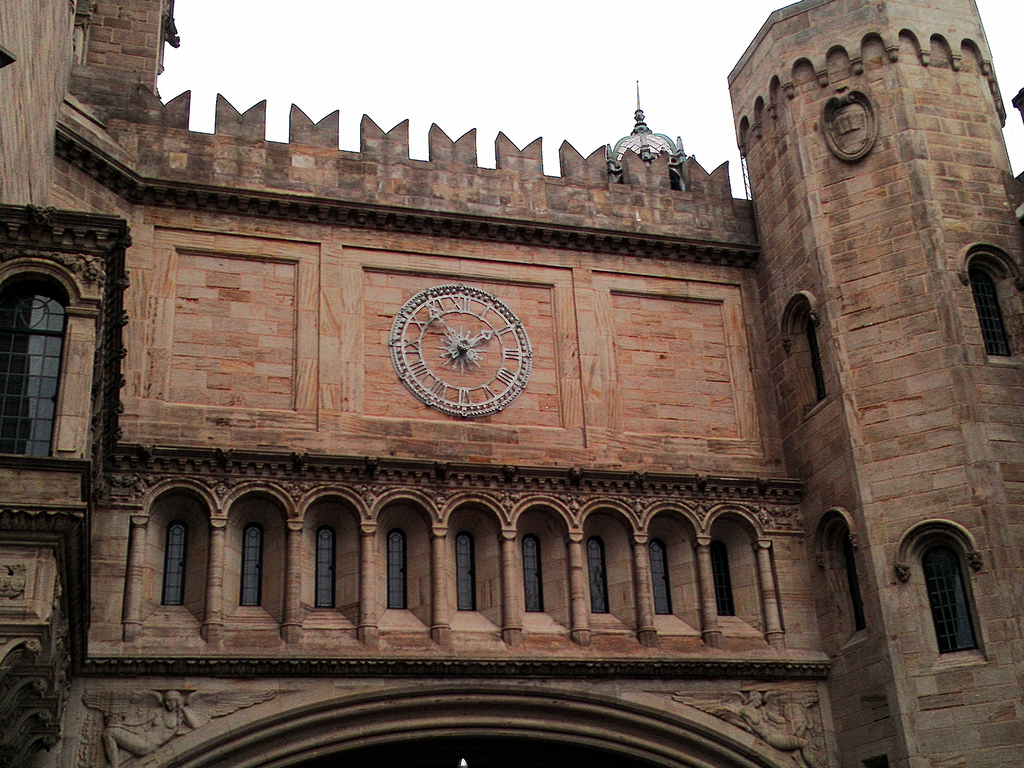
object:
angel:
[425, 302, 496, 374]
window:
[710, 540, 737, 617]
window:
[521, 532, 545, 612]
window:
[239, 522, 266, 607]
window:
[161, 519, 189, 606]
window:
[647, 536, 672, 614]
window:
[586, 535, 610, 614]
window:
[455, 531, 477, 613]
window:
[388, 528, 408, 610]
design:
[342, 245, 589, 449]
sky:
[181, 0, 728, 89]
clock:
[388, 282, 535, 418]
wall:
[87, 83, 834, 677]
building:
[0, 0, 1022, 764]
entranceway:
[276, 734, 668, 765]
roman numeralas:
[484, 367, 516, 401]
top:
[726, 0, 1008, 156]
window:
[893, 510, 999, 670]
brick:
[106, 83, 760, 247]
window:
[0, 247, 107, 471]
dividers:
[0, 295, 65, 457]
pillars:
[120, 515, 785, 647]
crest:
[821, 89, 879, 161]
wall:
[789, 34, 1022, 767]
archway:
[120, 679, 801, 766]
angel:
[671, 689, 821, 766]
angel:
[80, 686, 275, 760]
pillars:
[202, 518, 230, 628]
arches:
[509, 495, 577, 533]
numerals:
[403, 297, 520, 405]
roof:
[607, 134, 687, 177]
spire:
[630, 79, 652, 135]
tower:
[726, 1, 1022, 767]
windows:
[824, 519, 867, 632]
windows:
[956, 241, 1024, 365]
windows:
[788, 301, 829, 419]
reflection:
[955, 567, 975, 649]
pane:
[922, 545, 979, 654]